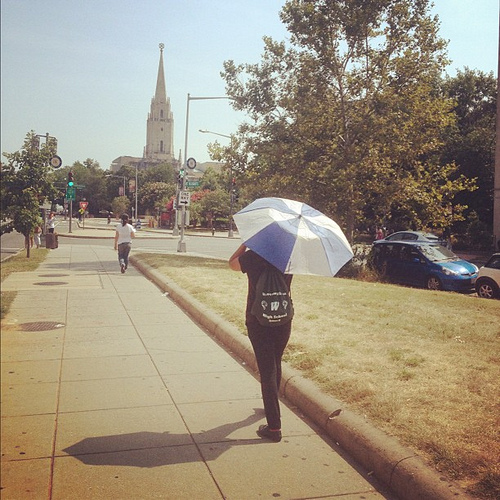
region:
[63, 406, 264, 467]
A shadow on the ground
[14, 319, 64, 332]
A manhole on the sidewalk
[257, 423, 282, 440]
A shoe on the left foot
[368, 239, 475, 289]
A blue car parked on the street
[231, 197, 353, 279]
An umbrella in the woman's hands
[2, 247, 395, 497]
The sidewalk by the road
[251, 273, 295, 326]
The girl is wearing a small backpack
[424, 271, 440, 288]
The front tire on the car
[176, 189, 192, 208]
A traffic sign on the post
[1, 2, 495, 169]
The sky above the sidewalk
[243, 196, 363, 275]
blue and white umbrella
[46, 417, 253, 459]
shadow on the ground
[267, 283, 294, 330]
writing on the backpack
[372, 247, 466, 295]
blue car is parked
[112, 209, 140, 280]
person walking down the street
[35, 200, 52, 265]
people standing at the corner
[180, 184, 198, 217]
dircetion sign pointing right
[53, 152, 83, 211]
signal light is green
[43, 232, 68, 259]
wasted disposal on the corner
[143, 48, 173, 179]
high cathedral building in the distance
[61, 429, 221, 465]
shadow of person on pavement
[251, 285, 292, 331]
writing on back of shirt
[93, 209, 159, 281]
person walking down the street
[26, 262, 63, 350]
manhole covers on the pavement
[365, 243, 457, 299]
blue car parked by curb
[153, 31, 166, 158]
tall cathedral in the distance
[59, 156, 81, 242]
signal light at the corner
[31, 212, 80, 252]
people waiting to cross the street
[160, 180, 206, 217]
directional sign pointing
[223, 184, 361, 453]
A pedestrian holding a blue and white umbrella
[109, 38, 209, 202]
an old church or cathedral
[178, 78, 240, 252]
a medal street light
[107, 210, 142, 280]
person walking towards the road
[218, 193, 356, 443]
person carrying an umbrella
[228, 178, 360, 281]
a blue and white umbrella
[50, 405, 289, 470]
person's shadow on the ground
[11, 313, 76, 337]
man hole cover on the sidewalk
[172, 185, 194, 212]
one way directional sign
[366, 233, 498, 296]
blue car parked against a curb